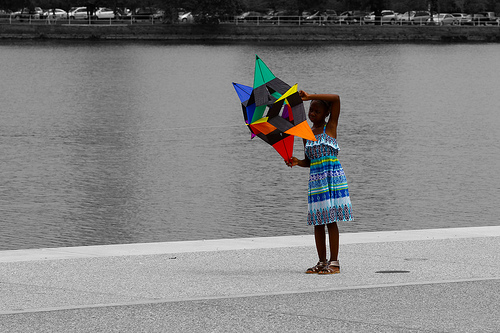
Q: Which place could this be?
A: It is a sidewalk.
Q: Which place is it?
A: It is a sidewalk.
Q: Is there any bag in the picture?
A: No, there are no bags.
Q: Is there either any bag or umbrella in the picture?
A: No, there are no bags or umbrellas.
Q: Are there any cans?
A: No, there are no cans.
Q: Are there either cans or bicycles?
A: No, there are no cans or bicycles.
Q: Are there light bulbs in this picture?
A: No, there are no light bulbs.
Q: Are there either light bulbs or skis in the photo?
A: No, there are no light bulbs or skis.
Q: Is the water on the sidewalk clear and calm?
A: Yes, the water is clear and calm.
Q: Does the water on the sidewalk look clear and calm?
A: Yes, the water is clear and calm.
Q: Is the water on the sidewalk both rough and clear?
A: No, the water is clear but calm.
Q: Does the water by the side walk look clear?
A: Yes, the water is clear.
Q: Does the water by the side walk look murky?
A: No, the water is clear.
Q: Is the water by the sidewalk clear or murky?
A: The water is clear.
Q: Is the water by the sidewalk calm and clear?
A: Yes, the water is calm and clear.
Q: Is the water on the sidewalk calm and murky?
A: No, the water is calm but clear.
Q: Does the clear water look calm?
A: Yes, the water is calm.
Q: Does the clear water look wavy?
A: No, the water is calm.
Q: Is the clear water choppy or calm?
A: The water is calm.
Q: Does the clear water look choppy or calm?
A: The water is calm.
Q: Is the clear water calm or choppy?
A: The water is calm.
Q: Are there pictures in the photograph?
A: No, there are no pictures.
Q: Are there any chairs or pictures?
A: No, there are no pictures or chairs.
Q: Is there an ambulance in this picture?
A: No, there are no ambulances.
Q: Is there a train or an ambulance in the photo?
A: No, there are no ambulances or trains.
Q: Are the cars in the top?
A: Yes, the cars are in the top of the image.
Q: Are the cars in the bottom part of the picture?
A: No, the cars are in the top of the image.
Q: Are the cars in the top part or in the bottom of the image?
A: The cars are in the top of the image.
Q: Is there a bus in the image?
A: No, there are no buses.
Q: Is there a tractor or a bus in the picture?
A: No, there are no buses or tractors.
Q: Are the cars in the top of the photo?
A: Yes, the cars are in the top of the image.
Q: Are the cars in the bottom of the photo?
A: No, the cars are in the top of the image.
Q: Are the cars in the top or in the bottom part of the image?
A: The cars are in the top of the image.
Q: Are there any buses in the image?
A: No, there are no buses.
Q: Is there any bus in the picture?
A: No, there are no buses.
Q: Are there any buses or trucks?
A: No, there are no buses or trucks.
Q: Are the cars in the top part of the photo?
A: Yes, the cars are in the top of the image.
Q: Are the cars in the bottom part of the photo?
A: No, the cars are in the top of the image.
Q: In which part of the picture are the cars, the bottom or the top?
A: The cars are in the top of the image.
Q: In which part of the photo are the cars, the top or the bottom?
A: The cars are in the top of the image.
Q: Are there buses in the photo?
A: No, there are no buses.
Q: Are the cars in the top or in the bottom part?
A: The cars are in the top of the image.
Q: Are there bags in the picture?
A: No, there are no bags.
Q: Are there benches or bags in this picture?
A: No, there are no bags or benches.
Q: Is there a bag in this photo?
A: No, there are no bags.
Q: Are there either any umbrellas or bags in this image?
A: No, there are no bags or umbrellas.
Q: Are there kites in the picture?
A: Yes, there is a kite.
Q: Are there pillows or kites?
A: Yes, there is a kite.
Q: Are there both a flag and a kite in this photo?
A: No, there is a kite but no flags.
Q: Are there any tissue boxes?
A: No, there are no tissue boxes.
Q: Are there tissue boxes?
A: No, there are no tissue boxes.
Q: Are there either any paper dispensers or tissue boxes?
A: No, there are no tissue boxes or paper dispensers.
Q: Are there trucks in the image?
A: No, there are no trucks.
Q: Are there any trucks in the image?
A: No, there are no trucks.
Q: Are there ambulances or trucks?
A: No, there are no trucks or ambulances.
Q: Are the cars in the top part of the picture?
A: Yes, the cars are in the top of the image.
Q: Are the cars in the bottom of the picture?
A: No, the cars are in the top of the image.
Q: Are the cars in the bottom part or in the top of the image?
A: The cars are in the top of the image.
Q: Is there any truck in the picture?
A: No, there are no trucks.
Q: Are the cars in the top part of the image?
A: Yes, the cars are in the top of the image.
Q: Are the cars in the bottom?
A: No, the cars are in the top of the image.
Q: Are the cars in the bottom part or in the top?
A: The cars are in the top of the image.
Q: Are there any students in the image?
A: No, there are no students.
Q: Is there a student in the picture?
A: No, there are no students.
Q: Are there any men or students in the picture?
A: No, there are no students or men.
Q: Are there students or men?
A: No, there are no students or men.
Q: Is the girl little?
A: Yes, the girl is little.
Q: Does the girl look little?
A: Yes, the girl is little.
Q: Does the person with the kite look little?
A: Yes, the girl is little.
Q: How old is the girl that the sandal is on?
A: The girl is little.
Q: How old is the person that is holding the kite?
A: The girl is little.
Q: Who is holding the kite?
A: The girl is holding the kite.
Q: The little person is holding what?
A: The girl is holding the kite.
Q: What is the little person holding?
A: The girl is holding the kite.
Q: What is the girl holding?
A: The girl is holding the kite.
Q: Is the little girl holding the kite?
A: Yes, the girl is holding the kite.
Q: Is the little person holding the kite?
A: Yes, the girl is holding the kite.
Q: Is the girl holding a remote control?
A: No, the girl is holding the kite.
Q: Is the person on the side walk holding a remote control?
A: No, the girl is holding the kite.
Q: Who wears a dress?
A: The girl wears a dress.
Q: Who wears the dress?
A: The girl wears a dress.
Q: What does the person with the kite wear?
A: The girl wears a dress.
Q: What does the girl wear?
A: The girl wears a dress.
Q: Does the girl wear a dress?
A: Yes, the girl wears a dress.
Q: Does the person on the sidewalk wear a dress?
A: Yes, the girl wears a dress.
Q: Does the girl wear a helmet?
A: No, the girl wears a dress.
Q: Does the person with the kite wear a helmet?
A: No, the girl wears a dress.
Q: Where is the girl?
A: The girl is on the sidewalk.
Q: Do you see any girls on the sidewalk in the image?
A: Yes, there is a girl on the sidewalk.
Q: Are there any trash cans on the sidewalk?
A: No, there is a girl on the sidewalk.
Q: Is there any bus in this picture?
A: No, there are no buses.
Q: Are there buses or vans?
A: No, there are no buses or vans.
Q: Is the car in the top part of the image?
A: Yes, the car is in the top of the image.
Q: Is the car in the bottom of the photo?
A: No, the car is in the top of the image.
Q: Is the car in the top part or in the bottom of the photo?
A: The car is in the top of the image.